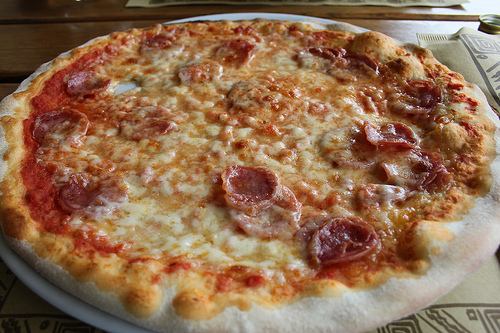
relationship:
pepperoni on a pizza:
[225, 160, 278, 207] [1, 18, 500, 332]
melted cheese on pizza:
[113, 50, 358, 253] [1, 18, 500, 332]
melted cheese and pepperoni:
[113, 50, 358, 253] [225, 160, 278, 207]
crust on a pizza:
[1, 209, 500, 332] [1, 18, 500, 332]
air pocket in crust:
[396, 212, 463, 260] [1, 209, 500, 332]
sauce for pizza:
[21, 47, 99, 246] [1, 18, 500, 332]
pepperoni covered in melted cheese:
[225, 160, 278, 207] [113, 50, 358, 253]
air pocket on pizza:
[396, 212, 463, 260] [1, 18, 500, 332]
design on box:
[367, 308, 499, 333] [381, 248, 500, 333]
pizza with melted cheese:
[1, 18, 500, 332] [113, 50, 358, 253]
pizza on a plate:
[1, 18, 500, 332] [1, 253, 138, 333]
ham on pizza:
[42, 166, 132, 218] [1, 18, 500, 332]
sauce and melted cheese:
[21, 47, 99, 246] [113, 50, 358, 253]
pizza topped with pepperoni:
[1, 18, 500, 332] [225, 160, 278, 207]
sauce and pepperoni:
[21, 47, 99, 246] [225, 160, 278, 207]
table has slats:
[1, 0, 495, 101] [1, 4, 495, 60]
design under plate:
[367, 308, 499, 333] [1, 253, 138, 333]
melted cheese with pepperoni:
[113, 50, 358, 253] [225, 160, 278, 207]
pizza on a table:
[1, 18, 500, 332] [1, 0, 495, 101]